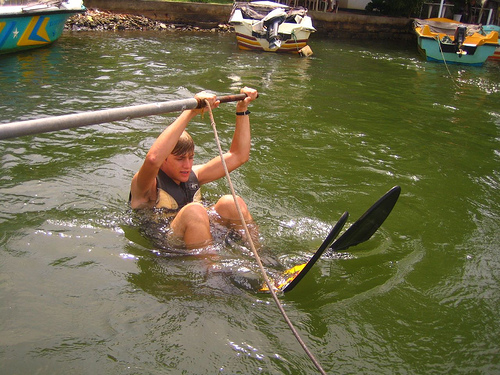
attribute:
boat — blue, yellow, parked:
[2, 2, 88, 55]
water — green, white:
[5, 30, 498, 374]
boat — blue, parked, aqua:
[411, 14, 499, 62]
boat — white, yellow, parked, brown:
[226, 0, 318, 59]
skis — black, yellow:
[231, 184, 403, 295]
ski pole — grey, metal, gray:
[0, 94, 262, 139]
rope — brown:
[204, 99, 326, 374]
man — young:
[128, 86, 262, 273]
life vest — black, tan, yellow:
[128, 170, 202, 229]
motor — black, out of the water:
[455, 25, 467, 56]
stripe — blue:
[427, 56, 483, 67]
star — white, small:
[11, 28, 20, 37]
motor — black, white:
[262, 7, 288, 53]